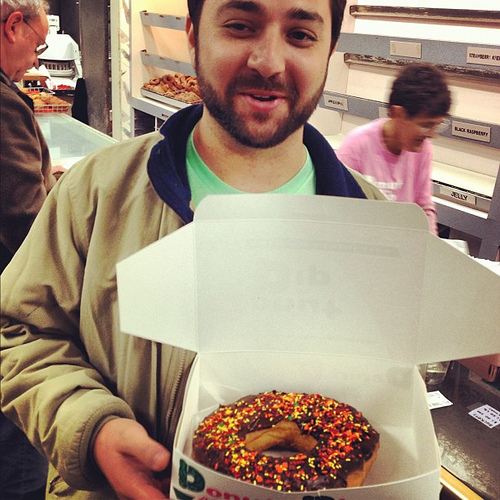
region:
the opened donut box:
[118, 190, 486, 499]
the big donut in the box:
[194, 391, 376, 497]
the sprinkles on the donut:
[246, 392, 322, 414]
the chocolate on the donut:
[305, 465, 335, 484]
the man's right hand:
[81, 411, 176, 498]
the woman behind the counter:
[345, 57, 451, 240]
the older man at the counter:
[2, 2, 70, 229]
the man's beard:
[182, 61, 328, 152]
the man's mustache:
[227, 72, 304, 95]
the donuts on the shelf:
[136, 69, 203, 99]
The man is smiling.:
[168, 0, 382, 156]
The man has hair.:
[165, 2, 361, 146]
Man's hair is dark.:
[167, 0, 365, 159]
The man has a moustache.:
[168, 0, 369, 164]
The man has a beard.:
[174, 2, 369, 171]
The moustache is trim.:
[170, 1, 369, 166]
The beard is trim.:
[176, 1, 357, 161]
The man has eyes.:
[171, 2, 365, 179]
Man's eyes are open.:
[172, 0, 368, 154]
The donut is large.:
[95, 182, 497, 499]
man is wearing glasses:
[2, 0, 63, 69]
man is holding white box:
[33, 4, 493, 496]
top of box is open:
[98, 171, 475, 376]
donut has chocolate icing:
[207, 331, 399, 497]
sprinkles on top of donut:
[198, 379, 367, 493]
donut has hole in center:
[236, 405, 321, 485]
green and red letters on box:
[170, 459, 260, 498]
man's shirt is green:
[178, 123, 349, 223]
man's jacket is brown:
[9, 80, 463, 430]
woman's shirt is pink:
[330, 107, 460, 216]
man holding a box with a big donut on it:
[0, 2, 361, 476]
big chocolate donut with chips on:
[187, 395, 372, 495]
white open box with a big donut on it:
[147, 198, 439, 498]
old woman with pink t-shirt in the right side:
[323, 64, 450, 234]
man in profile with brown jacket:
[0, 1, 54, 242]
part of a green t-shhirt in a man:
[185, 125, 327, 219]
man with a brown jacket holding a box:
[0, 10, 378, 494]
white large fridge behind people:
[127, 0, 491, 211]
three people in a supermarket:
[0, 18, 478, 493]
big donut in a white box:
[196, 387, 380, 485]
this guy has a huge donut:
[113, 22, 430, 498]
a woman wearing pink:
[364, 24, 479, 369]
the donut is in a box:
[130, 318, 327, 489]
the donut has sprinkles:
[134, 332, 351, 497]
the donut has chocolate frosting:
[137, 348, 282, 459]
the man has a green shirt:
[175, 24, 400, 264]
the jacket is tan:
[87, 74, 385, 368]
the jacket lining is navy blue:
[98, 101, 265, 252]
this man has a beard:
[150, 20, 411, 230]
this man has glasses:
[4, 12, 98, 194]